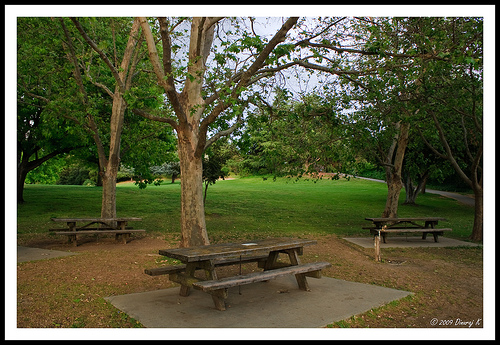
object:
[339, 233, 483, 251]
slab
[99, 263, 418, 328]
slab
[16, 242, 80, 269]
slab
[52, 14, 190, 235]
tree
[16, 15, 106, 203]
tree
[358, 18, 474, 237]
tree